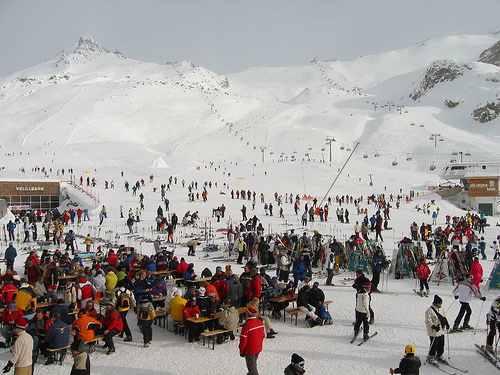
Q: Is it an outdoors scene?
A: Yes, it is outdoors.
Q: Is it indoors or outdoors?
A: It is outdoors.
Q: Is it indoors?
A: No, it is outdoors.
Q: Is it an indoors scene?
A: No, it is outdoors.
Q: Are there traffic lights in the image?
A: No, there are no traffic lights.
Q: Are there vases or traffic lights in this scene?
A: No, there are no traffic lights or vases.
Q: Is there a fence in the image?
A: No, there are no fences.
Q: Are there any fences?
A: No, there are no fences.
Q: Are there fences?
A: No, there are no fences.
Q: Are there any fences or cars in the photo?
A: No, there are no fences or cars.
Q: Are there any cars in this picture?
A: No, there are no cars.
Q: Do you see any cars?
A: No, there are no cars.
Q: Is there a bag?
A: No, there are no bags.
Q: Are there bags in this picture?
A: No, there are no bags.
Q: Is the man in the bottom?
A: Yes, the man is in the bottom of the image.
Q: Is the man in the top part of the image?
A: No, the man is in the bottom of the image.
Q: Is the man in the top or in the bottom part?
A: The man is in the bottom of the image.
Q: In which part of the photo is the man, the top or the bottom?
A: The man is in the bottom of the image.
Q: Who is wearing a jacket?
A: The man is wearing a jacket.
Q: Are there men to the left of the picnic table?
A: Yes, there is a man to the left of the picnic table.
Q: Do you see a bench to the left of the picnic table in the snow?
A: No, there is a man to the left of the picnic table.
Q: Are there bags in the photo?
A: No, there are no bags.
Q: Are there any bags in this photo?
A: No, there are no bags.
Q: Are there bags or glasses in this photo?
A: No, there are no bags or glasses.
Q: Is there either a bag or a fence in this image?
A: No, there are no fences or bags.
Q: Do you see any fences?
A: No, there are no fences.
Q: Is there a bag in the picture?
A: No, there are no bags.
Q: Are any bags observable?
A: No, there are no bags.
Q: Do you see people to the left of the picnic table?
A: Yes, there is a person to the left of the picnic table.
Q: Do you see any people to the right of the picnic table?
A: No, the person is to the left of the picnic table.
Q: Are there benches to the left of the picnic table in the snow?
A: No, there is a person to the left of the picnic table.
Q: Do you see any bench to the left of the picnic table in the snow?
A: No, there is a person to the left of the picnic table.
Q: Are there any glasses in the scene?
A: No, there are no glasses.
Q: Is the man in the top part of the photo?
A: No, the man is in the bottom of the image.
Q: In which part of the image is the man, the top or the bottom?
A: The man is in the bottom of the image.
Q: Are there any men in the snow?
A: Yes, there is a man in the snow.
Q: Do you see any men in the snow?
A: Yes, there is a man in the snow.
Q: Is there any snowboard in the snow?
A: No, there is a man in the snow.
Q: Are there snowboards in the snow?
A: No, there is a man in the snow.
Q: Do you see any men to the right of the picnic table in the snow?
A: Yes, there is a man to the right of the picnic table.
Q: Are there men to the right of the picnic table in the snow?
A: Yes, there is a man to the right of the picnic table.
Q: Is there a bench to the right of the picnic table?
A: No, there is a man to the right of the picnic table.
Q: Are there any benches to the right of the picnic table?
A: No, there is a man to the right of the picnic table.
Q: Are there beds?
A: No, there are no beds.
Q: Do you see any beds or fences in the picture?
A: No, there are no beds or fences.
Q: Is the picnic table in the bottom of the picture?
A: Yes, the picnic table is in the bottom of the image.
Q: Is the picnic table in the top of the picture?
A: No, the picnic table is in the bottom of the image.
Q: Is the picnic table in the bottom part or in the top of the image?
A: The picnic table is in the bottom of the image.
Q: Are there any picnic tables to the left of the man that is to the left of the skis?
A: Yes, there is a picnic table to the left of the man.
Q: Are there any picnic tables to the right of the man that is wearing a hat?
A: No, the picnic table is to the left of the man.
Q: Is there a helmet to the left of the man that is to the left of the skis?
A: No, there is a picnic table to the left of the man.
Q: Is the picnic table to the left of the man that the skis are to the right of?
A: Yes, the picnic table is to the left of the man.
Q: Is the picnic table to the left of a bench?
A: No, the picnic table is to the left of the man.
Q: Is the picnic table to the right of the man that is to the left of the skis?
A: No, the picnic table is to the left of the man.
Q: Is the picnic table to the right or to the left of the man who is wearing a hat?
A: The picnic table is to the left of the man.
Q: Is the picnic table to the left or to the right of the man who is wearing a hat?
A: The picnic table is to the left of the man.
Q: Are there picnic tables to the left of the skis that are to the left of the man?
A: Yes, there is a picnic table to the left of the skis.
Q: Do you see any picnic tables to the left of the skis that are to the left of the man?
A: Yes, there is a picnic table to the left of the skis.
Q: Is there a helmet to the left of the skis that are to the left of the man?
A: No, there is a picnic table to the left of the skis.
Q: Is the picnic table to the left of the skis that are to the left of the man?
A: Yes, the picnic table is to the left of the skis.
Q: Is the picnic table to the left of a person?
A: No, the picnic table is to the right of a person.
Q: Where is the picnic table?
A: The picnic table is in the snow.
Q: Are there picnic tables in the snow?
A: Yes, there is a picnic table in the snow.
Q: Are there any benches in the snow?
A: No, there is a picnic table in the snow.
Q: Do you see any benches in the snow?
A: No, there is a picnic table in the snow.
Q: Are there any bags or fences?
A: No, there are no bags or fences.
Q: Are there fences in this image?
A: No, there are no fences.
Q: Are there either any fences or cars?
A: No, there are no fences or cars.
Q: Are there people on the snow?
A: Yes, there are people on the snow.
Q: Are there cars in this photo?
A: No, there are no cars.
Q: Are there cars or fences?
A: No, there are no cars or fences.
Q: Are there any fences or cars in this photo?
A: No, there are no cars or fences.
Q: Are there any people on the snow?
A: Yes, there are people on the snow.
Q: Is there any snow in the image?
A: Yes, there is snow.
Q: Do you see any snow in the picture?
A: Yes, there is snow.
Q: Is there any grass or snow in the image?
A: Yes, there is snow.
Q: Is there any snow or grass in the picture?
A: Yes, there is snow.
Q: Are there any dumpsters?
A: No, there are no dumpsters.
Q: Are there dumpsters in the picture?
A: No, there are no dumpsters.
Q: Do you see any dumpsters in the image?
A: No, there are no dumpsters.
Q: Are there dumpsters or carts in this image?
A: No, there are no dumpsters or carts.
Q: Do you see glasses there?
A: No, there are no glasses.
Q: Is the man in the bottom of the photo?
A: Yes, the man is in the bottom of the image.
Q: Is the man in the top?
A: No, the man is in the bottom of the image.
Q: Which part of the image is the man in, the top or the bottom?
A: The man is in the bottom of the image.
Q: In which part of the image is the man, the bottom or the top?
A: The man is in the bottom of the image.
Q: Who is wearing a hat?
A: The man is wearing a hat.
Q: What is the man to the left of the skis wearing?
A: The man is wearing a hat.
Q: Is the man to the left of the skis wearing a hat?
A: Yes, the man is wearing a hat.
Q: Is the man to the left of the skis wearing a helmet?
A: No, the man is wearing a hat.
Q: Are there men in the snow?
A: Yes, there is a man in the snow.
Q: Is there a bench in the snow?
A: No, there is a man in the snow.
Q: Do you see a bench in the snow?
A: No, there is a man in the snow.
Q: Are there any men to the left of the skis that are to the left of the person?
A: Yes, there is a man to the left of the skis.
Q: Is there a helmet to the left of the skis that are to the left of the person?
A: No, there is a man to the left of the skis.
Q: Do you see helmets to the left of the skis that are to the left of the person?
A: No, there is a man to the left of the skis.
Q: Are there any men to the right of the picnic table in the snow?
A: Yes, there is a man to the right of the picnic table.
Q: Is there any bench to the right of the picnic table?
A: No, there is a man to the right of the picnic table.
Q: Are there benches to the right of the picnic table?
A: No, there is a man to the right of the picnic table.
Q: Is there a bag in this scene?
A: No, there are no bags.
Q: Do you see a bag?
A: No, there are no bags.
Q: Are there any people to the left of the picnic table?
A: Yes, there is a person to the left of the picnic table.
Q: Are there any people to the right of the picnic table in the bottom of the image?
A: No, the person is to the left of the picnic table.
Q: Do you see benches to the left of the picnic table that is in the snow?
A: No, there is a person to the left of the picnic table.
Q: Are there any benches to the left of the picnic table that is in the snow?
A: No, there is a person to the left of the picnic table.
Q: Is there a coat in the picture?
A: Yes, there is a coat.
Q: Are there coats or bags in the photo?
A: Yes, there is a coat.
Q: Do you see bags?
A: No, there are no bags.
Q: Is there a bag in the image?
A: No, there are no bags.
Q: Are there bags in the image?
A: No, there are no bags.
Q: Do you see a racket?
A: No, there are no rackets.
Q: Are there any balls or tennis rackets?
A: No, there are no tennis rackets or balls.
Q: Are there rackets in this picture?
A: No, there are no rackets.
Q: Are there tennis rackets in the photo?
A: No, there are no tennis rackets.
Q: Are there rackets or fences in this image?
A: No, there are no rackets or fences.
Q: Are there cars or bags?
A: No, there are no cars or bags.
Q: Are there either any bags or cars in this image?
A: No, there are no cars or bags.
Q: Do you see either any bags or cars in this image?
A: No, there are no cars or bags.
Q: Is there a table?
A: Yes, there is a table.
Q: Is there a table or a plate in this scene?
A: Yes, there is a table.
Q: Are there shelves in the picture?
A: No, there are no shelves.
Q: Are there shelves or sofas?
A: No, there are no shelves or sofas.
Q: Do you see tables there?
A: Yes, there is a table.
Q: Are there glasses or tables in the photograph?
A: Yes, there is a table.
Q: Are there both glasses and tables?
A: No, there is a table but no glasses.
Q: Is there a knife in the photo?
A: No, there are no knives.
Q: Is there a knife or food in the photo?
A: No, there are no knives or food.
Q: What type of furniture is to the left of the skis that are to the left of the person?
A: The piece of furniture is a table.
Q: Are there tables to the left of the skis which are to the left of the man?
A: Yes, there is a table to the left of the skis.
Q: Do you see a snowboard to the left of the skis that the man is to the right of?
A: No, there is a table to the left of the skis.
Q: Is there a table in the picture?
A: Yes, there is a table.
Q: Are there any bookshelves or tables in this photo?
A: Yes, there is a table.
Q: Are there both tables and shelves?
A: No, there is a table but no shelves.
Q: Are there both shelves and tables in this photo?
A: No, there is a table but no shelves.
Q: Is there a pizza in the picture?
A: No, there are no pizzas.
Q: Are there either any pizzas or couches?
A: No, there are no pizzas or couches.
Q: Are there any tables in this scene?
A: Yes, there is a table.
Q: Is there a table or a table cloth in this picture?
A: Yes, there is a table.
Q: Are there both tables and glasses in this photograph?
A: No, there is a table but no glasses.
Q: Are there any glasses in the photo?
A: No, there are no glasses.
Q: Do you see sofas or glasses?
A: No, there are no glasses or sofas.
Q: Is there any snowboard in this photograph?
A: No, there are no snowboards.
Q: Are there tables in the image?
A: Yes, there is a table.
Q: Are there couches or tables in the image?
A: Yes, there is a table.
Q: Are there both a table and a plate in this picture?
A: No, there is a table but no plates.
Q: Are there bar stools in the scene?
A: No, there are no bar stools.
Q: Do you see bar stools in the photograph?
A: No, there are no bar stools.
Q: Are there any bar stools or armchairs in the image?
A: No, there are no bar stools or armchairs.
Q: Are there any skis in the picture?
A: Yes, there are skis.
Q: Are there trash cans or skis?
A: Yes, there are skis.